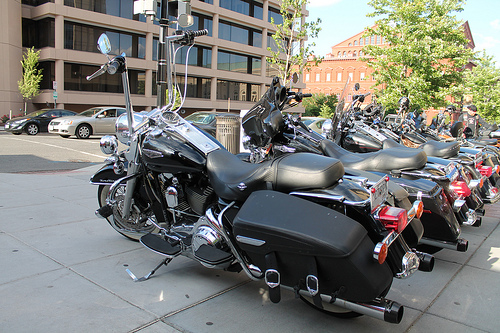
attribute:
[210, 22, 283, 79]
building — office, brick, brown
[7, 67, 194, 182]
area — parking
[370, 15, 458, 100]
tree — young, small, green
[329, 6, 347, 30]
sky — blue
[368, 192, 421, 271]
light — red, brake, bike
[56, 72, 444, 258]
street — city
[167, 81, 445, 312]
motorcycle — parked, black, silver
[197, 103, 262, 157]
can — trash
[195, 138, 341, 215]
seat — black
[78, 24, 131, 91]
mirror — rear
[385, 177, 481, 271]
plate — license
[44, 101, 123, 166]
road — portion, car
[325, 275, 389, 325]
pipe — exhaust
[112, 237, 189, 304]
stand — kick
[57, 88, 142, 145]
car — silver, green